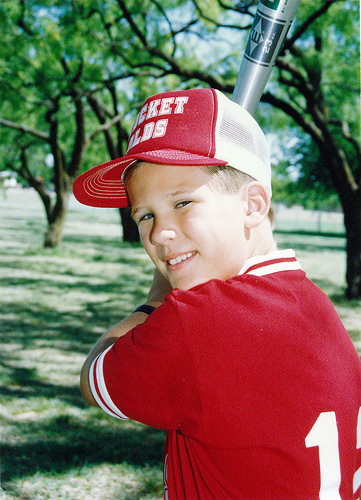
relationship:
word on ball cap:
[127, 90, 193, 133] [72, 86, 272, 209]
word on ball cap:
[125, 115, 170, 157] [72, 86, 272, 209]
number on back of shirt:
[303, 401, 360, 498] [87, 246, 360, 498]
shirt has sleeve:
[87, 246, 360, 498] [87, 294, 203, 446]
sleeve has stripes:
[87, 294, 203, 446] [85, 339, 130, 421]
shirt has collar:
[87, 246, 360, 498] [237, 246, 303, 278]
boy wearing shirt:
[71, 85, 360, 497] [87, 246, 360, 498]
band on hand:
[136, 303, 153, 317] [143, 265, 173, 303]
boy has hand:
[71, 85, 360, 497] [143, 265, 173, 303]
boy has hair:
[71, 85, 360, 497] [199, 159, 277, 228]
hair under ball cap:
[199, 159, 277, 228] [72, 86, 272, 209]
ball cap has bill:
[72, 86, 272, 209] [72, 147, 226, 208]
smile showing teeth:
[162, 245, 198, 271] [166, 248, 198, 265]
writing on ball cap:
[129, 102, 174, 145] [72, 86, 272, 209]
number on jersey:
[304, 410, 342, 499] [83, 252, 352, 491]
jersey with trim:
[77, 250, 336, 497] [79, 340, 133, 427]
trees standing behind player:
[7, 3, 357, 268] [87, 83, 331, 497]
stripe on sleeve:
[77, 343, 131, 428] [91, 291, 199, 432]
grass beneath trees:
[27, 402, 86, 453] [2, 58, 56, 187]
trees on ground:
[0, 2, 361, 298] [48, 438, 124, 491]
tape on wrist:
[133, 303, 157, 314] [130, 288, 164, 324]